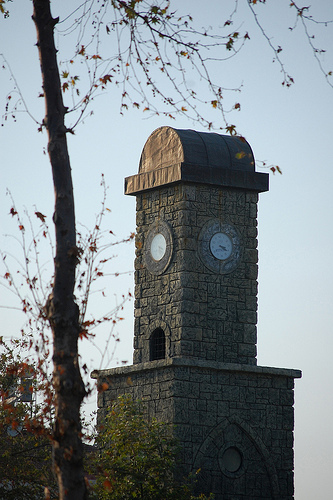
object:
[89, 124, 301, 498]
clock tower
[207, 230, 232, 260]
clock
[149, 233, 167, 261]
clocks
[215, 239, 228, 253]
hands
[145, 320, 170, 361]
door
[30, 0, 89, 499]
tree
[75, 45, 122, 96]
leaves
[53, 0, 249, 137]
branches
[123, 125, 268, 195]
dome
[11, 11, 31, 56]
sky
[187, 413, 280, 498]
arch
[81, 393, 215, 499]
leaves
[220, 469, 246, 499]
gate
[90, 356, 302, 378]
ledge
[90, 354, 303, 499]
base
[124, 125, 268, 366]
top